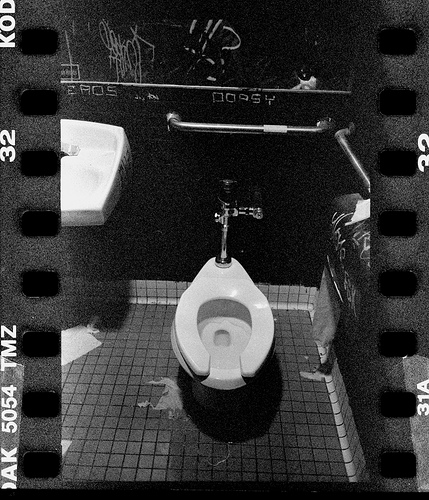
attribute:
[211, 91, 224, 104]
d — letter 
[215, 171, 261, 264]
pipe — silver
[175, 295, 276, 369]
toilet bowl — empty, clear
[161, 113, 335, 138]
handle bars. — silver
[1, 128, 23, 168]
number — Photo , 32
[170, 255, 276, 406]
toilet bowl — white, porcelain